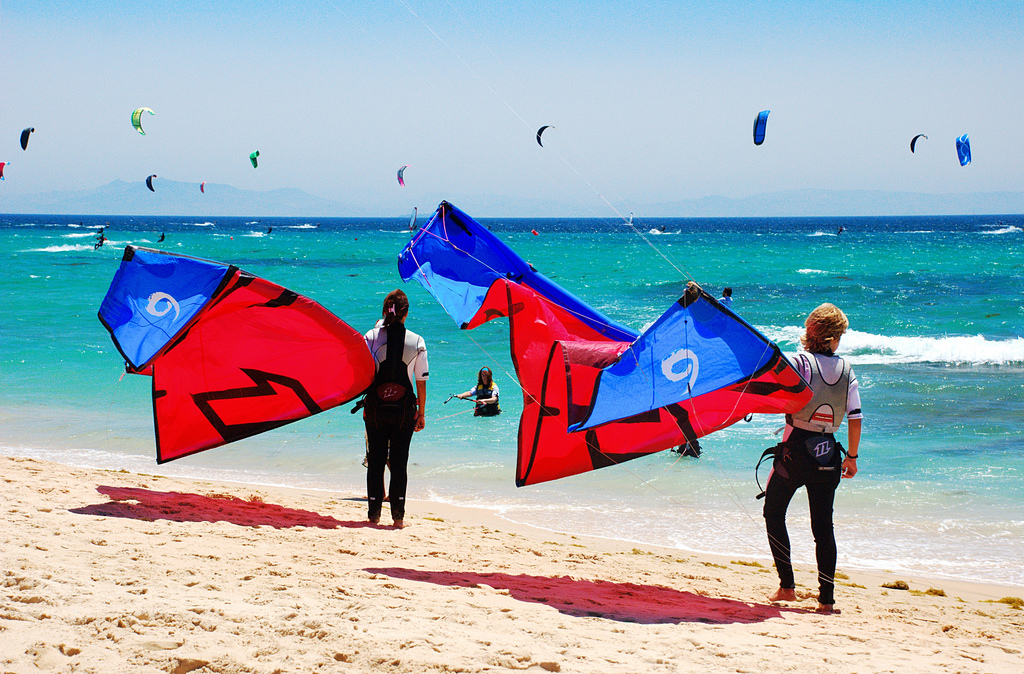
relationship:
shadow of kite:
[355, 556, 792, 640] [393, 197, 817, 495]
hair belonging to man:
[806, 302, 852, 351] [759, 291, 861, 617]